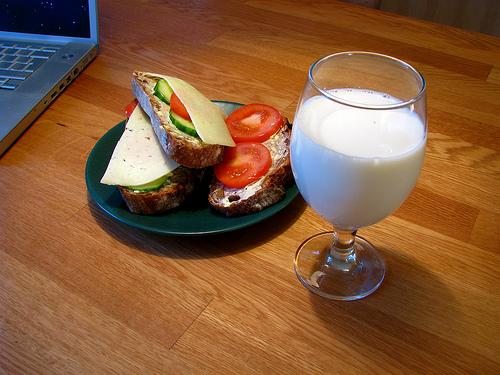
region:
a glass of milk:
[287, 44, 447, 283]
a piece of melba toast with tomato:
[232, 93, 293, 225]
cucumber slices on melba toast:
[145, 73, 203, 155]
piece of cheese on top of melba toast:
[105, 133, 173, 195]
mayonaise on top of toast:
[208, 185, 265, 214]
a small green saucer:
[97, 98, 250, 264]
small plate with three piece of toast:
[91, 56, 316, 271]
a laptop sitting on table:
[10, 4, 135, 149]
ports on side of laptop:
[35, 50, 73, 132]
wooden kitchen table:
[161, 24, 494, 156]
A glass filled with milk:
[288, 47, 434, 301]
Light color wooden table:
[32, 244, 258, 371]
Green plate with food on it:
[86, 71, 303, 241]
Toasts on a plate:
[91, 66, 232, 176]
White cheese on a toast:
[163, 71, 230, 147]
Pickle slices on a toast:
[151, 73, 200, 141]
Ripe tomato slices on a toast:
[220, 98, 272, 198]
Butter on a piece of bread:
[261, 122, 293, 192]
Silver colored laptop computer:
[0, 0, 108, 155]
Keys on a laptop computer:
[14, 41, 48, 77]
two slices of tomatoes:
[219, 96, 279, 227]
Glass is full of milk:
[287, 47, 429, 301]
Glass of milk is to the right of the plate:
[289, 50, 429, 304]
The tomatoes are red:
[213, 102, 283, 188]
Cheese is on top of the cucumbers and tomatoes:
[98, 101, 163, 187]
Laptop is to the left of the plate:
[0, 0, 100, 156]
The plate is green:
[83, 97, 303, 237]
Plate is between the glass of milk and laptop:
[83, 97, 307, 240]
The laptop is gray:
[0, 0, 102, 162]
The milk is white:
[287, 86, 429, 232]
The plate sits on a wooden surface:
[85, 97, 305, 238]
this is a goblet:
[263, 24, 448, 328]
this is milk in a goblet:
[260, 22, 444, 312]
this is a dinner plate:
[79, 50, 327, 277]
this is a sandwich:
[93, 56, 283, 239]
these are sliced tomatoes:
[214, 85, 287, 224]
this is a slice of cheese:
[149, 62, 233, 152]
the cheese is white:
[139, 47, 230, 147]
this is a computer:
[5, 0, 110, 154]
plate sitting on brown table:
[82, 70, 290, 275]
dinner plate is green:
[58, 85, 299, 255]